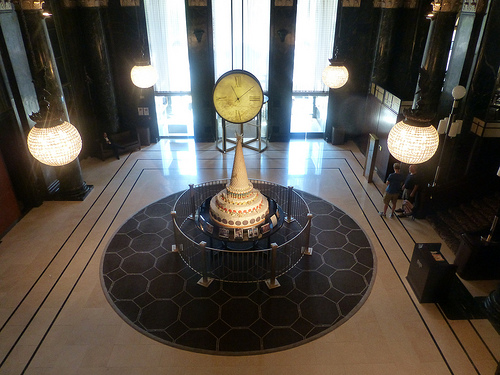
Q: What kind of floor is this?
A: Tile.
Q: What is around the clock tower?
A: A fence.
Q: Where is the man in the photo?
A: Left of the windows.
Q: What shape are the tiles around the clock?
A: Octagons.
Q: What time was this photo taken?
A: 11:10am.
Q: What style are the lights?
A: Globes.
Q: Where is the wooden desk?
A: Right of the clock.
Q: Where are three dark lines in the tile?
A: Around the clock.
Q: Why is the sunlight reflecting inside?
A: It is very sunny outside.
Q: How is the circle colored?
A: Brown.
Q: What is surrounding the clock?
A: Barrier.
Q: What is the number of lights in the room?
A: Four.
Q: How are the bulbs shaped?
A: Circle.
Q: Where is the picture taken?
A: A lobby.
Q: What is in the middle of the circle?
A: A clock.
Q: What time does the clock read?
A: 11:05.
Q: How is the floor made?
A: Of marble.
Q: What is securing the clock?
A: A railing.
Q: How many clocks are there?
A: One.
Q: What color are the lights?
A: White.